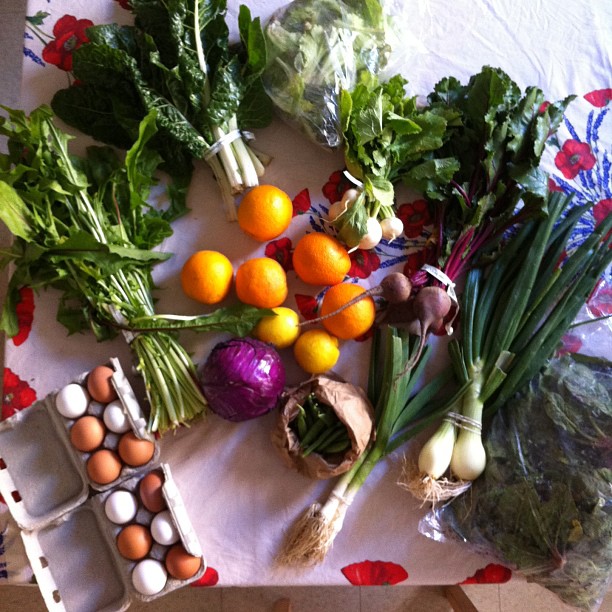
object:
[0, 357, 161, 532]
egg carton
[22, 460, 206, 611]
egg carton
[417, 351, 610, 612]
herbs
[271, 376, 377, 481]
vegetable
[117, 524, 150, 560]
egg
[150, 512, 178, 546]
egg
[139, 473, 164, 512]
egg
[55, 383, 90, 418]
egg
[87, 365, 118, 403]
egg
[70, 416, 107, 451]
egg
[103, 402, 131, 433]
egg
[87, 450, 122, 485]
egg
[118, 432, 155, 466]
egg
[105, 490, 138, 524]
egg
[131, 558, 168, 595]
egg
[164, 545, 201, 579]
egg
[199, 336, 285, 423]
onion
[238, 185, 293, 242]
fruit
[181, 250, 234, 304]
fruit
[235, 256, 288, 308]
fruit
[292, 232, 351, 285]
fruit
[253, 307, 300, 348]
fruit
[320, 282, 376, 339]
fruit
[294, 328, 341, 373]
fruit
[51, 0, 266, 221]
vegetable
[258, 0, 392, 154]
vegetable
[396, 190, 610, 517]
vegetable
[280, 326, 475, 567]
vegetable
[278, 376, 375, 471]
vegetable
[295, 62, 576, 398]
beets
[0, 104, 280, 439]
leafy vegetable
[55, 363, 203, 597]
eggs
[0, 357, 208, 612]
carton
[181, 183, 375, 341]
oranges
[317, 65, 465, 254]
cabbage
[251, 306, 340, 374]
lemons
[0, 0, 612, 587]
table